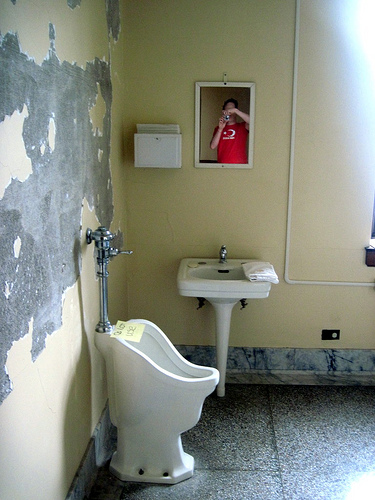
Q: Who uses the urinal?
A: Men.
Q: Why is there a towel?
A: To dry hands.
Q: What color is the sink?
A: White.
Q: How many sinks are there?
A: One.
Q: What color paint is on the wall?
A: Yellow.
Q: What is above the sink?
A: Mirror.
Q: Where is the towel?
A: On the sink.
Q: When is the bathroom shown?
A: Daytime.